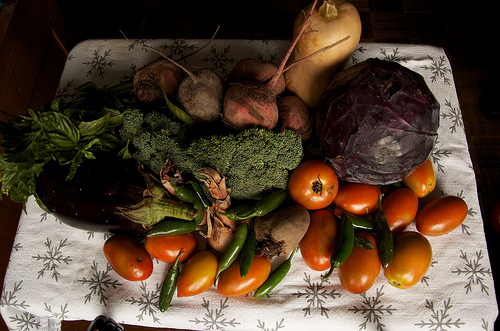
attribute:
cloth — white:
[4, 38, 497, 328]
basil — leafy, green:
[39, 109, 81, 152]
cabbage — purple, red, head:
[317, 55, 443, 184]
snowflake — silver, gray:
[30, 236, 72, 286]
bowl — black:
[30, 152, 144, 235]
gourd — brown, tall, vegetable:
[283, 0, 362, 114]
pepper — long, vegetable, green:
[317, 211, 352, 282]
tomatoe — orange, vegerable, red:
[414, 190, 470, 236]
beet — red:
[223, 7, 316, 128]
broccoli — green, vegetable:
[188, 126, 304, 201]